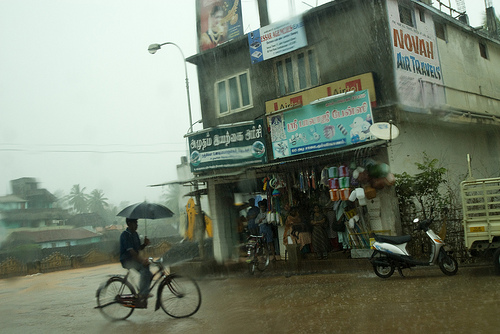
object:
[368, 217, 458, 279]
moped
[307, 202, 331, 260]
girl standing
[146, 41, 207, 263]
street light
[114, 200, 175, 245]
umbrella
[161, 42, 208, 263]
post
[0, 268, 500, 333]
ground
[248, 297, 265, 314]
droplets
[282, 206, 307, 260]
people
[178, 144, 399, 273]
shop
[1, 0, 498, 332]
rain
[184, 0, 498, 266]
building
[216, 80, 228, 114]
window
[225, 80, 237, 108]
window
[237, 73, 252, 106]
window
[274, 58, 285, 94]
window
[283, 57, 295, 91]
window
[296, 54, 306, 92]
window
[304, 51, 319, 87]
window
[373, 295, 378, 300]
droplet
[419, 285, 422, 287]
droplet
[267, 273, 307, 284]
droplet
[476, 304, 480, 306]
droplet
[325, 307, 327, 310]
droplet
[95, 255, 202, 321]
bicycle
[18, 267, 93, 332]
water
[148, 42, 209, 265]
lamp post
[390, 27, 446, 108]
advertisement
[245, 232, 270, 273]
bike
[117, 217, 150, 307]
man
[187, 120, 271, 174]
signs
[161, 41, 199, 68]
post light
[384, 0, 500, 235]
wall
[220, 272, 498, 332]
water droplets